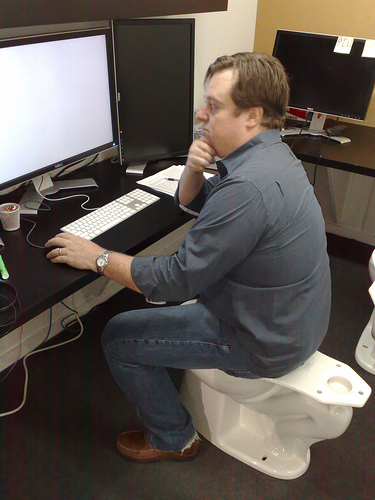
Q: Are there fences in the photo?
A: No, there are no fences.